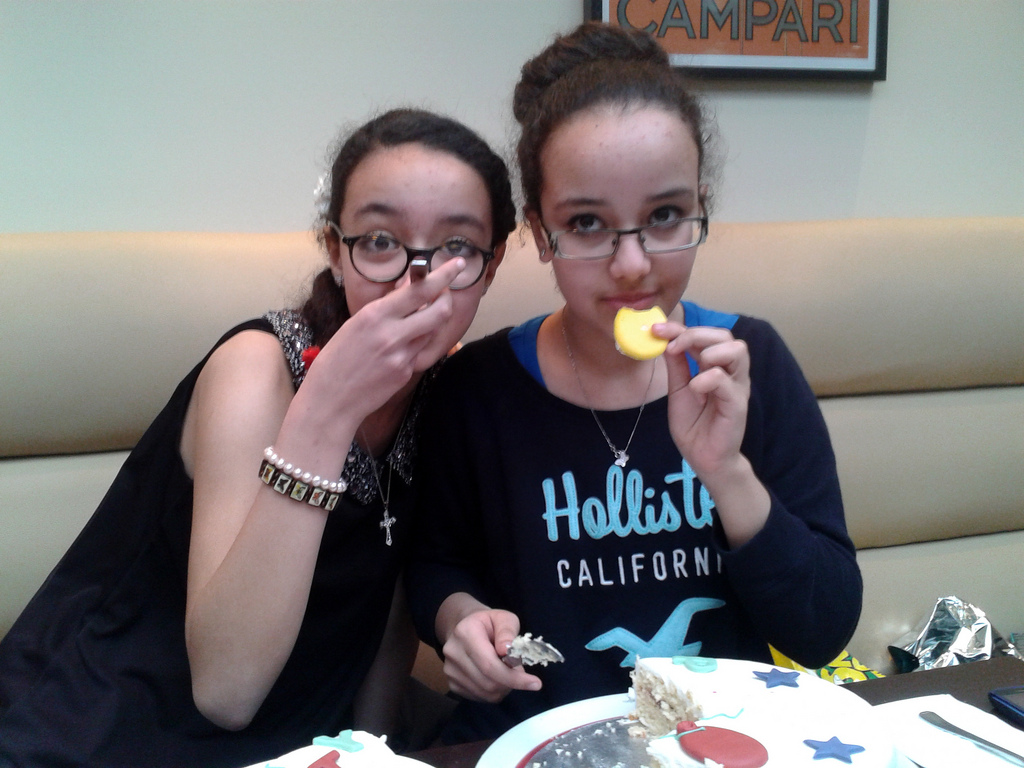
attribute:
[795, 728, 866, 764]
star — blue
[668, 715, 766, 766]
circle — red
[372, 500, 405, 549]
cross — silver